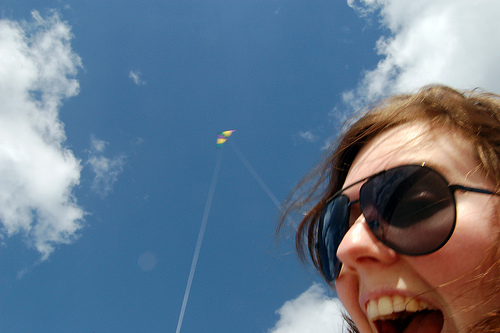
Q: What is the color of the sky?
A: Blue.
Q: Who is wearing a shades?
A: The woman.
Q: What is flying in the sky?
A: A kite.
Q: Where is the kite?
A: In the sky.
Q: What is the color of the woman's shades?
A: Black.